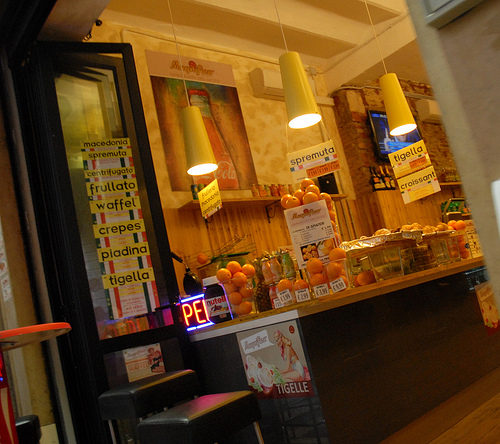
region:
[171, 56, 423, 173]
Three lights hanging from ceiling.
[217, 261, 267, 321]
Oranges in container on counter.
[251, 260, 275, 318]
Pineapple sitting on counter.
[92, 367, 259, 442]
Two stools next to counter.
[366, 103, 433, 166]
TV mounted on wall of building.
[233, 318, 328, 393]
Advertisement sign on side of counter.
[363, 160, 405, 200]
Liquor bottles on shelf below TV.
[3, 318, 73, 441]
Edge of red table.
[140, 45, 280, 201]
Picture on wall behind counter.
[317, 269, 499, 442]
Wood base support for counter.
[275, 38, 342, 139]
the hanging light in middle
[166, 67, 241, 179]
the left hanigng light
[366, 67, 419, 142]
the right hanging light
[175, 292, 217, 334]
a light up sign blue and yellow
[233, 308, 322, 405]
a red and white poster on counter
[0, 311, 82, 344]
orange top of a table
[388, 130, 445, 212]
a sign hanging from celing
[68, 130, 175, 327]
sticker words on a glass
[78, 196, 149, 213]
the word waffel in black and yellow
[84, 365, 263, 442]
two leather stools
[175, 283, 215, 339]
letters on neon sign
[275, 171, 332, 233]
pile of oranges behind sign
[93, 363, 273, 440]
two stools with black seats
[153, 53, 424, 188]
three lights suspended from ceiling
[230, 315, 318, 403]
sign under counter top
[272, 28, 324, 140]
long modern light on cable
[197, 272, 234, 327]
jar with white lid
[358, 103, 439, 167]
flat screen television on wall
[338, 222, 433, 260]
tray with tin foil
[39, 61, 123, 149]
window of open door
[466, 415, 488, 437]
part of a floor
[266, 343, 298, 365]
part of a banner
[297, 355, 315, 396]
edge of a post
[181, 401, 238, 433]
edge of a seat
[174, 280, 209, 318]
part of a poster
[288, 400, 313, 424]
part of a glasss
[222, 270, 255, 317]
part of an orange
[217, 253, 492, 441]
a large counter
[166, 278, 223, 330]
a neon sign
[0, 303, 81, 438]
a table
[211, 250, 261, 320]
oranges in a glass pitcher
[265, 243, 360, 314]
oranges in several glasses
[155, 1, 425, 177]
lights with yellow metal shades suspended from above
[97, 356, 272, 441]
dark cushioned stools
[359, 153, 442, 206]
bottles on a shelf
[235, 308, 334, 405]
poster with image of a woman beneath counter